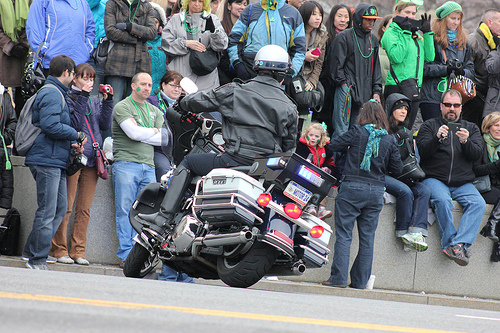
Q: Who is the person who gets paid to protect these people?
A: The bike policeman.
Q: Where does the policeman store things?
A: Bike bags.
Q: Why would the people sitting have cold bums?
A: Sitting on cement wall.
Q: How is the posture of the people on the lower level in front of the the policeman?
A: Standing.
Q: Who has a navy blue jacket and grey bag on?
A: Man in front of the policeman.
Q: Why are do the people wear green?
A: St. Patrick's Day.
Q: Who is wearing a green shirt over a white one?
A: Bald man in front.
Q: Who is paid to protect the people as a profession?
A: Policeman.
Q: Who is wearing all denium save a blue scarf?
A: Woman in front.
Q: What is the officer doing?
A: Driving.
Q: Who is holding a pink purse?
A: Woman on the left.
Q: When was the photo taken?
A: The morning.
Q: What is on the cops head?
A: Helmet.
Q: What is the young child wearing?
A: Coat.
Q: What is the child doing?
A: Sitting.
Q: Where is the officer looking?
A: To the right.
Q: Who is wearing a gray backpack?
A: Man on the left.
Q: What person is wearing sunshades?
A: Man sitting.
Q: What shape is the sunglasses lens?
A: Square.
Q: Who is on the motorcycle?
A: A police officer.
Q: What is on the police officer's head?
A: A helmet.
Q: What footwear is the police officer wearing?
A: Boots.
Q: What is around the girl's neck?
A: A scarf.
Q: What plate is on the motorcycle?
A: A license plate.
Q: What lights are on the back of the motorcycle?
A: Brake lights.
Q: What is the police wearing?
A: A black jacket.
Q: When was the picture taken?
A: Daytime.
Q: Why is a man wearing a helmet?
A: Man is riding a motorcycle.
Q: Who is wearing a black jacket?
A: Motorbike rider.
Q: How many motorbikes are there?
A: One.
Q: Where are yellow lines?
A: On the street.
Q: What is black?
A: Tires.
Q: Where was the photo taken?
A: On the street.